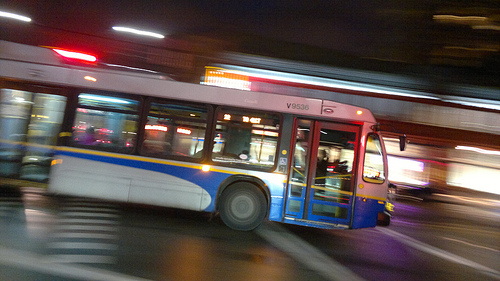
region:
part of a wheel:
[218, 174, 265, 270]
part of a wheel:
[232, 182, 265, 225]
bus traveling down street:
[5, 39, 391, 242]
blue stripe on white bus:
[68, 152, 381, 229]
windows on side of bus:
[78, 94, 276, 169]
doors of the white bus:
[283, 114, 362, 221]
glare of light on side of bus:
[182, 157, 212, 174]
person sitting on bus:
[77, 120, 97, 141]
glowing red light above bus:
[65, 52, 97, 69]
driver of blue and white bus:
[310, 144, 339, 187]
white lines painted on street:
[3, 193, 466, 276]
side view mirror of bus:
[389, 120, 412, 152]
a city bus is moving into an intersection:
[3, 45, 400, 242]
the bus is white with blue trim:
[7, 44, 393, 239]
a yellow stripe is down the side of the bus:
[7, 130, 364, 205]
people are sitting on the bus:
[71, 119, 248, 169]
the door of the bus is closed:
[293, 118, 360, 233]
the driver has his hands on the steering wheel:
[306, 137, 358, 177]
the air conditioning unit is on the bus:
[3, 40, 64, 80]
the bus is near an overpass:
[28, 25, 498, 258]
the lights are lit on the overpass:
[6, 9, 493, 135]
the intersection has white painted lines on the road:
[23, 190, 498, 275]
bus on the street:
[21, 74, 428, 256]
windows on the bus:
[56, 97, 288, 194]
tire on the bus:
[213, 170, 283, 238]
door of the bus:
[278, 112, 370, 211]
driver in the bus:
[309, 130, 348, 185]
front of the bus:
[254, 85, 440, 250]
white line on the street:
[392, 231, 459, 278]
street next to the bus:
[225, 238, 320, 278]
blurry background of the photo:
[140, 25, 296, 79]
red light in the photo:
[61, 35, 111, 74]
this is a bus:
[66, 88, 351, 233]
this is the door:
[313, 122, 345, 229]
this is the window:
[222, 110, 274, 162]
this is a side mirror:
[396, 130, 411, 150]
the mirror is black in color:
[391, 124, 413, 167]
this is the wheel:
[220, 183, 258, 231]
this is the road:
[88, 223, 200, 279]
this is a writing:
[283, 95, 313, 111]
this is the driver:
[321, 147, 334, 174]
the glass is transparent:
[153, 114, 209, 150]